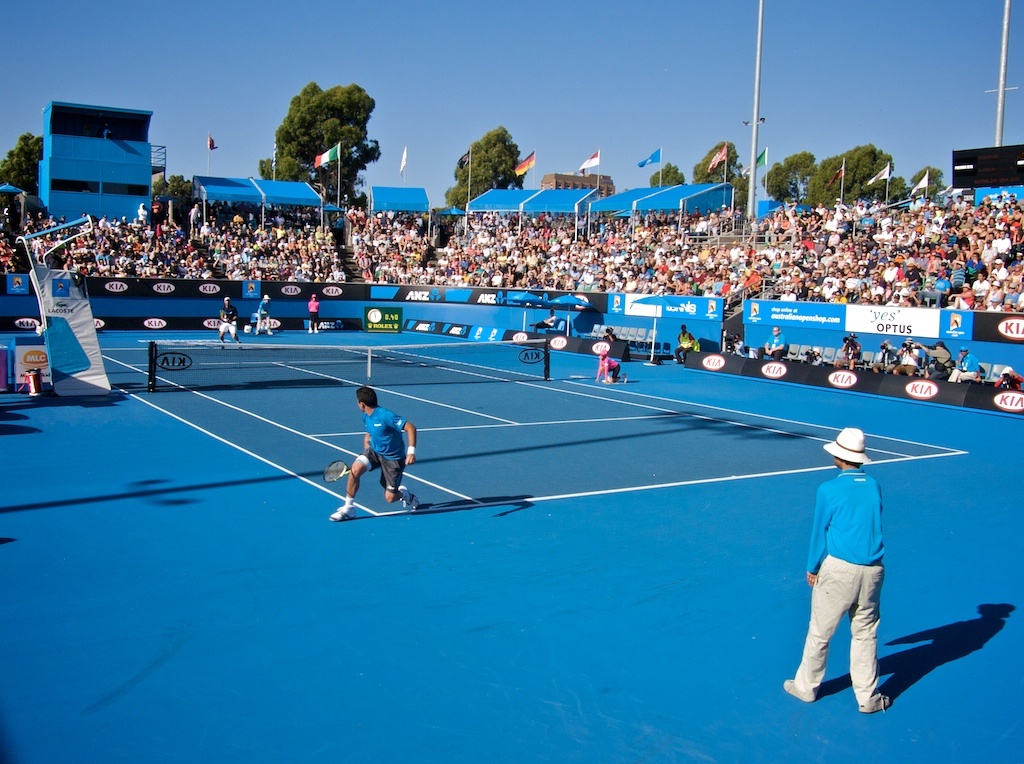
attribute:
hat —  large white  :
[819, 419, 878, 467]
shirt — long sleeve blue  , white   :
[797, 463, 893, 578]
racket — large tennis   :
[318, 456, 361, 486]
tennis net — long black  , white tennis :
[133, 331, 567, 388]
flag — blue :
[635, 144, 665, 173]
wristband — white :
[398, 442, 419, 455]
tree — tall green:
[265, 74, 387, 204]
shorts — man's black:
[354, 438, 406, 497]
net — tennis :
[135, 333, 559, 398]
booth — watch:
[15, 213, 117, 401]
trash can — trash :
[15, 362, 47, 401]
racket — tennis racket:
[324, 451, 354, 481]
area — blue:
[32, 94, 165, 235]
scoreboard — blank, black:
[941, 143, 1021, 197]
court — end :
[52, 280, 994, 732]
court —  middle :
[75, 321, 991, 739]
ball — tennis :
[233, 293, 279, 330]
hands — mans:
[348, 458, 359, 478]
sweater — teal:
[806, 465, 882, 567]